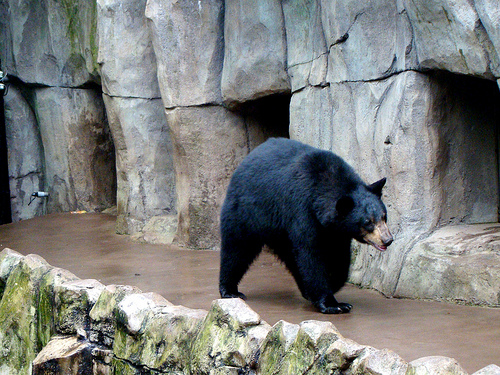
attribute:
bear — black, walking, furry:
[218, 138, 395, 315]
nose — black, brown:
[380, 231, 392, 246]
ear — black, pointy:
[335, 197, 355, 219]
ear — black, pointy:
[366, 176, 387, 199]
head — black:
[316, 180, 393, 251]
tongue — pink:
[376, 243, 390, 249]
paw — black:
[218, 288, 246, 301]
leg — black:
[220, 224, 264, 287]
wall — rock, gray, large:
[4, 2, 499, 309]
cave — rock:
[421, 71, 500, 267]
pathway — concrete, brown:
[0, 211, 500, 372]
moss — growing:
[62, 1, 100, 65]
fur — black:
[219, 138, 386, 314]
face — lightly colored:
[335, 178, 397, 253]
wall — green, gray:
[2, 244, 498, 374]